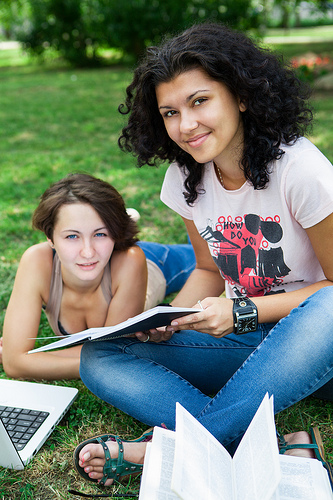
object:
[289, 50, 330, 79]
rose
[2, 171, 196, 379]
person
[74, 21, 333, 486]
girl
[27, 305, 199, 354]
book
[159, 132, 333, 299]
shirt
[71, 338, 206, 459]
jean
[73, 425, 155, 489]
sandal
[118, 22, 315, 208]
hair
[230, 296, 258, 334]
watch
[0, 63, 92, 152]
grass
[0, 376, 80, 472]
laptop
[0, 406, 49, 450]
keyboard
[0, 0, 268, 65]
tree